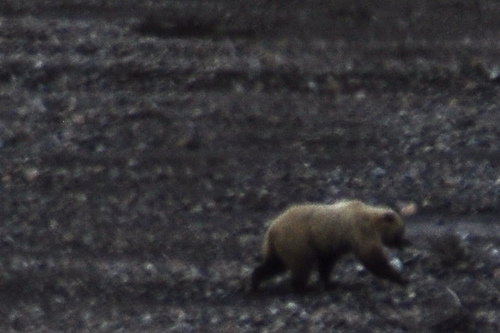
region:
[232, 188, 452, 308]
Black and brown bear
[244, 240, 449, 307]
Four black legs on bear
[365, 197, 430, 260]
Brown and black bear head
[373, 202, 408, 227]
One small black bear ear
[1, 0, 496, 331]
Black rock ground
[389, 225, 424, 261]
Open mouth on brown bear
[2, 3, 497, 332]
Small white rocks on dark ground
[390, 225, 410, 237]
Small eye on bear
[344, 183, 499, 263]
Small grey path on ground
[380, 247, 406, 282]
Small white rock behind bear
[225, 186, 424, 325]
Brown bear walking around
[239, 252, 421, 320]
Four black legs on brown bear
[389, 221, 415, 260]
Open black mouth on bear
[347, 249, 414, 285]
Small white rocks behind bear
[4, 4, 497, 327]
Black rocky ground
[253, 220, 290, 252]
Small brown bear tail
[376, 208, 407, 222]
Small black bear ear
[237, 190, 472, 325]
Bear walking to the right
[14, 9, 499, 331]
Small white rocks all over the ground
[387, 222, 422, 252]
Black muzzle on bear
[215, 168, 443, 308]
the bear is walking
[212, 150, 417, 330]
the bear is brown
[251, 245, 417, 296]
bear's legs are black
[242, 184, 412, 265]
top of bear is brown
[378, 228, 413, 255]
bear's nose and mouth are black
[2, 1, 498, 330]
ground made of dirt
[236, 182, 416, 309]
bear walking by himself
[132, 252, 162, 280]
white part of ground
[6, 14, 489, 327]
the ground is wet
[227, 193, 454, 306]
bear is walking towards right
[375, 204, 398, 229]
bear's ear is dark brown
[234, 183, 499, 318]
a bear walking outside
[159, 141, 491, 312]
a bear walking in a field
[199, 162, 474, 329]
a bear walking on the ground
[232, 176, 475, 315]
a brown bear walking outside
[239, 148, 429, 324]
a brown bear walking in a field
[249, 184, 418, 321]
a brown bear walking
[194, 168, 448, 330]
an area with a bear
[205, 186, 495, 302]
an area with brown bear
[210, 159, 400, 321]
a bear on all fours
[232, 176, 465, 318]
a brown bear on all fours